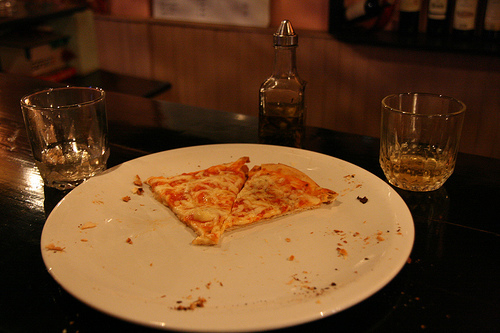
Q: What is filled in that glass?
A: Scotch.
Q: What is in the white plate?
A: Pizza.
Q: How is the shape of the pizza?
A: Small and thin.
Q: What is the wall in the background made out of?
A: Wood.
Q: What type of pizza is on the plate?
A: Cheese pizza.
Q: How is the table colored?
A: Black.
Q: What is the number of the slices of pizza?
A: Two.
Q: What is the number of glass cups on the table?
A: Two.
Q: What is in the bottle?
A: Olive oil.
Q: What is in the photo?
A: Food and drink.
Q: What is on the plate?
A: Food.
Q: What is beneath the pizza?
A: Plate.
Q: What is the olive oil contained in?
A: Glass bottle.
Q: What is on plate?
A: PIzza.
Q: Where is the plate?
A: On the table.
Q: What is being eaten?
A: Pizza.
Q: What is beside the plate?
A: Bottle of oil.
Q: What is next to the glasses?
A: Plate.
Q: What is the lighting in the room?
A: Dim.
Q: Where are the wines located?
A: In rack.